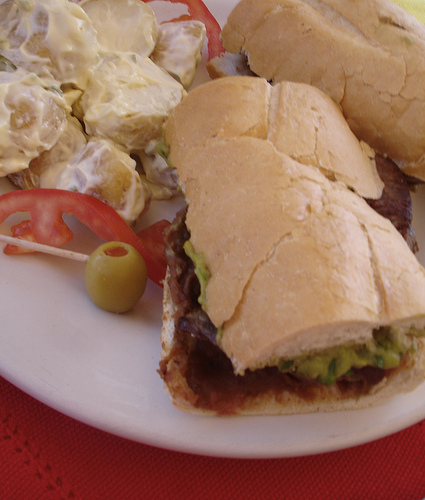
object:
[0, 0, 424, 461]
plate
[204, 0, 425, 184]
food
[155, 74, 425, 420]
food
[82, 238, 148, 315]
food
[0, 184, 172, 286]
food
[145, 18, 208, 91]
food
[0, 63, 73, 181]
food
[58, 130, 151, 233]
potatos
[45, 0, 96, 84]
suace